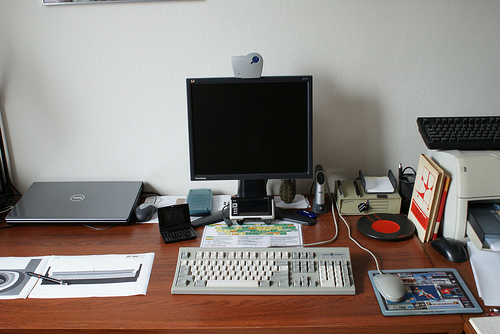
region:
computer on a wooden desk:
[165, 28, 369, 300]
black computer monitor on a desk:
[179, 51, 327, 235]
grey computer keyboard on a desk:
[162, 236, 359, 306]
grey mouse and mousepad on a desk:
[357, 233, 482, 325]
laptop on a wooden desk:
[10, 151, 144, 246]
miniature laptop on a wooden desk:
[146, 191, 208, 257]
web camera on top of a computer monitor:
[174, 31, 323, 191]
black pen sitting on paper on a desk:
[18, 237, 165, 312]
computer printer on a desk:
[435, 106, 497, 260]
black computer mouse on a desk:
[418, 215, 488, 279]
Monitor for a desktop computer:
[168, 62, 326, 227]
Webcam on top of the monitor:
[210, 45, 276, 86]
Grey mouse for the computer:
[350, 246, 415, 311]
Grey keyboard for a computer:
[165, 236, 360, 306]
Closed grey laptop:
[5, 157, 156, 247]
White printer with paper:
[400, 135, 495, 270]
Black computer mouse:
[415, 225, 485, 270]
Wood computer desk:
[1, 171, 488, 326]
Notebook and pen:
[11, 235, 162, 305]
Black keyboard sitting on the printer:
[402, 101, 497, 161]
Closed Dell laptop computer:
[5, 178, 137, 223]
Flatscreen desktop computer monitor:
[185, 75, 315, 177]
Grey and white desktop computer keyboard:
[172, 242, 352, 292]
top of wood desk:
[26, 296, 371, 326]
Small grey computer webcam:
[311, 162, 326, 212]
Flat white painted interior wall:
[5, 10, 177, 175]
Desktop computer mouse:
[371, 270, 403, 300]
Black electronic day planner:
[150, 200, 195, 240]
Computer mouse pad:
[400, 266, 470, 311]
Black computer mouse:
[430, 232, 467, 258]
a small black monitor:
[175, 72, 318, 206]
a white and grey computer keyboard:
[167, 244, 359, 299]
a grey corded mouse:
[364, 267, 410, 307]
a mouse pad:
[370, 261, 480, 318]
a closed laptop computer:
[9, 178, 144, 222]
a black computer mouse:
[428, 229, 467, 269]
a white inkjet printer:
[430, 150, 498, 257]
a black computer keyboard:
[411, 107, 498, 151]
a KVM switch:
[328, 177, 398, 215]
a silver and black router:
[308, 159, 331, 213]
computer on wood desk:
[178, 69, 316, 238]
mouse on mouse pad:
[370, 260, 410, 307]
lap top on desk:
[19, 167, 134, 229]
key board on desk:
[162, 231, 357, 296]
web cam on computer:
[223, 42, 267, 87]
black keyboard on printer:
[412, 104, 497, 156]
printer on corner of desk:
[442, 144, 497, 259]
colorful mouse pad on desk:
[369, 269, 478, 316]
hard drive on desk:
[315, 165, 330, 214]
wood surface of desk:
[229, 298, 294, 325]